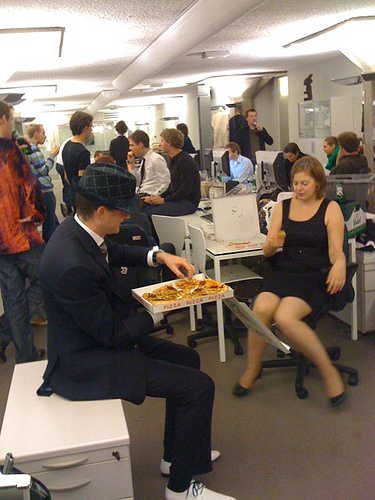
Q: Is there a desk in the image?
A: Yes, there is a desk.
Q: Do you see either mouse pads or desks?
A: Yes, there is a desk.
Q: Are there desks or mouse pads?
A: Yes, there is a desk.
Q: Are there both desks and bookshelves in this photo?
A: No, there is a desk but no bookshelves.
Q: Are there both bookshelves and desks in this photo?
A: No, there is a desk but no bookshelves.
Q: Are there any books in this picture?
A: No, there are no books.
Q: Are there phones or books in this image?
A: No, there are no books or phones.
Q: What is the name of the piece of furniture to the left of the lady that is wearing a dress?
A: The piece of furniture is a desk.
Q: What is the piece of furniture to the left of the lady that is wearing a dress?
A: The piece of furniture is a desk.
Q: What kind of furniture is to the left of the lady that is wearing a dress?
A: The piece of furniture is a desk.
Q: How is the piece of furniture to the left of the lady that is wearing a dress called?
A: The piece of furniture is a desk.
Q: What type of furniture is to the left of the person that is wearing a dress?
A: The piece of furniture is a desk.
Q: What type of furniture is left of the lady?
A: The piece of furniture is a desk.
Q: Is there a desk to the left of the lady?
A: Yes, there is a desk to the left of the lady.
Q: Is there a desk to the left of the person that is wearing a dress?
A: Yes, there is a desk to the left of the lady.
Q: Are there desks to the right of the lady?
A: No, the desk is to the left of the lady.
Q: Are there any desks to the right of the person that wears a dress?
A: No, the desk is to the left of the lady.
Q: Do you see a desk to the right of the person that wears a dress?
A: No, the desk is to the left of the lady.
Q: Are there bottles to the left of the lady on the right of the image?
A: No, there is a desk to the left of the lady.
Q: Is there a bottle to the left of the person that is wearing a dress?
A: No, there is a desk to the left of the lady.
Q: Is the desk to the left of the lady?
A: Yes, the desk is to the left of the lady.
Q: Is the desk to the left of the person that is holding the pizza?
A: Yes, the desk is to the left of the lady.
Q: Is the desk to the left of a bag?
A: No, the desk is to the left of the lady.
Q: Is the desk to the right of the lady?
A: No, the desk is to the left of the lady.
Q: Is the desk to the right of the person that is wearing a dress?
A: No, the desk is to the left of the lady.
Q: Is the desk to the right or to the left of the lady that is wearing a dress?
A: The desk is to the left of the lady.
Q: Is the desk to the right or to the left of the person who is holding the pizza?
A: The desk is to the left of the lady.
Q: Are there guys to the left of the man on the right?
A: Yes, there is a guy to the left of the man.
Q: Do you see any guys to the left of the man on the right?
A: Yes, there is a guy to the left of the man.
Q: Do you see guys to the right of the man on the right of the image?
A: No, the guy is to the left of the man.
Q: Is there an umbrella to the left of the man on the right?
A: No, there is a guy to the left of the man.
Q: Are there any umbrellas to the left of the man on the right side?
A: No, there is a guy to the left of the man.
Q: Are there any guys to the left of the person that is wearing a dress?
A: Yes, there is a guy to the left of the lady.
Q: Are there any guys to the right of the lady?
A: No, the guy is to the left of the lady.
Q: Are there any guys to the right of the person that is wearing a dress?
A: No, the guy is to the left of the lady.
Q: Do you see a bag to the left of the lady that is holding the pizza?
A: No, there is a guy to the left of the lady.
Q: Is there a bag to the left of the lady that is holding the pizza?
A: No, there is a guy to the left of the lady.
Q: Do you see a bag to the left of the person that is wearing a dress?
A: No, there is a guy to the left of the lady.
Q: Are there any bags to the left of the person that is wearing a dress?
A: No, there is a guy to the left of the lady.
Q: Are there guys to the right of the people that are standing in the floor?
A: Yes, there is a guy to the right of the people.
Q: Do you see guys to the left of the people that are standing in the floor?
A: No, the guy is to the right of the people.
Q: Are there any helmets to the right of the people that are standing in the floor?
A: No, there is a guy to the right of the people.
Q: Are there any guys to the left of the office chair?
A: Yes, there is a guy to the left of the office chair.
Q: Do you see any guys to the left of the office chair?
A: Yes, there is a guy to the left of the office chair.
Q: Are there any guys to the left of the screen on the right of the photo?
A: Yes, there is a guy to the left of the screen.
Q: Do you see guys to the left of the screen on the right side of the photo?
A: Yes, there is a guy to the left of the screen.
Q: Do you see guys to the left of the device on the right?
A: Yes, there is a guy to the left of the screen.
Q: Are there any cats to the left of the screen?
A: No, there is a guy to the left of the screen.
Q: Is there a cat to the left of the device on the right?
A: No, there is a guy to the left of the screen.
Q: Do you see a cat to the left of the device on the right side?
A: No, there is a guy to the left of the screen.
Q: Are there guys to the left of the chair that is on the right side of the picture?
A: Yes, there is a guy to the left of the chair.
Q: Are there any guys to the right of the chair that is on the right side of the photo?
A: No, the guy is to the left of the chair.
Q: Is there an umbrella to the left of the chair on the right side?
A: No, there is a guy to the left of the chair.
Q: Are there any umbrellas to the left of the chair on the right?
A: No, there is a guy to the left of the chair.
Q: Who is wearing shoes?
A: The guy is wearing shoes.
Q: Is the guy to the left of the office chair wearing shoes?
A: Yes, the guy is wearing shoes.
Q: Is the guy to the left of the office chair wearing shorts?
A: No, the guy is wearing shoes.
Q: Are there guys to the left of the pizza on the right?
A: Yes, there is a guy to the left of the pizza.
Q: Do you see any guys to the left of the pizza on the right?
A: Yes, there is a guy to the left of the pizza.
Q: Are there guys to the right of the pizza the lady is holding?
A: No, the guy is to the left of the pizza.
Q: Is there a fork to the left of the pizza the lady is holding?
A: No, there is a guy to the left of the pizza.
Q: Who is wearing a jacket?
A: The guy is wearing a jacket.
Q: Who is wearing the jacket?
A: The guy is wearing a jacket.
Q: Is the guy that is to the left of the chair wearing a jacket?
A: Yes, the guy is wearing a jacket.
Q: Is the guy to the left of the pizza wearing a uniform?
A: No, the guy is wearing a jacket.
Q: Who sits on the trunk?
A: The guy sits on the trunk.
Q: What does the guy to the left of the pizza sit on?
A: The guy sits on the trunk.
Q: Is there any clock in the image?
A: No, there are no clocks.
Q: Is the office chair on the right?
A: Yes, the office chair is on the right of the image.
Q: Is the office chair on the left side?
A: No, the office chair is on the right of the image.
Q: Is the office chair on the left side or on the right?
A: The office chair is on the right of the image.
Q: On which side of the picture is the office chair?
A: The office chair is on the right of the image.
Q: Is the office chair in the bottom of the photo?
A: Yes, the office chair is in the bottom of the image.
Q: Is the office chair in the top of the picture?
A: No, the office chair is in the bottom of the image.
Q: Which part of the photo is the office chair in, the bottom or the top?
A: The office chair is in the bottom of the image.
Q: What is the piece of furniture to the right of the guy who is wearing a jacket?
A: The piece of furniture is an office chair.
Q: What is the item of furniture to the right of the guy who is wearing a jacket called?
A: The piece of furniture is an office chair.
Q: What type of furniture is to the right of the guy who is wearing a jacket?
A: The piece of furniture is an office chair.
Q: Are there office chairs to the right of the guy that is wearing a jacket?
A: Yes, there is an office chair to the right of the guy.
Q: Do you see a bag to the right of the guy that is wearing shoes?
A: No, there is an office chair to the right of the guy.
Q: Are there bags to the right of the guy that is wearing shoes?
A: No, there is an office chair to the right of the guy.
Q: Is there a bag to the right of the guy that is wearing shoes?
A: No, there is an office chair to the right of the guy.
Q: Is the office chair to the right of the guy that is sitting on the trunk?
A: Yes, the office chair is to the right of the guy.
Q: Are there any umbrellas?
A: No, there are no umbrellas.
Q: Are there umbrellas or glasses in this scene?
A: No, there are no umbrellas or glasses.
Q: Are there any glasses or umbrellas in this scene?
A: No, there are no umbrellas or glasses.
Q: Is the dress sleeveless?
A: Yes, the dress is sleeveless.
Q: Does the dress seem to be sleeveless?
A: Yes, the dress is sleeveless.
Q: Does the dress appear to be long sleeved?
A: No, the dress is sleeveless.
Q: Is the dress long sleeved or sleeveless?
A: The dress is sleeveless.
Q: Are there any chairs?
A: Yes, there is a chair.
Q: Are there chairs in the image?
A: Yes, there is a chair.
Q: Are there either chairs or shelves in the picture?
A: Yes, there is a chair.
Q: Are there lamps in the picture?
A: No, there are no lamps.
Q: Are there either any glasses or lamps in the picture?
A: No, there are no lamps or glasses.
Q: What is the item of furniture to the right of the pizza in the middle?
A: The piece of furniture is a chair.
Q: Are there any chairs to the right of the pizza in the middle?
A: Yes, there is a chair to the right of the pizza.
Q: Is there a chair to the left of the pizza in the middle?
A: No, the chair is to the right of the pizza.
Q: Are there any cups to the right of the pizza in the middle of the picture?
A: No, there is a chair to the right of the pizza.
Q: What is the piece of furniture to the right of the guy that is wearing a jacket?
A: The piece of furniture is a chair.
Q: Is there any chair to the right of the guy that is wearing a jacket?
A: Yes, there is a chair to the right of the guy.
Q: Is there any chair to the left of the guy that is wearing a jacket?
A: No, the chair is to the right of the guy.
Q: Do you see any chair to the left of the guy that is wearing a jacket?
A: No, the chair is to the right of the guy.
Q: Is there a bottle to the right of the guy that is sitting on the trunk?
A: No, there is a chair to the right of the guy.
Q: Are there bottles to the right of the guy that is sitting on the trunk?
A: No, there is a chair to the right of the guy.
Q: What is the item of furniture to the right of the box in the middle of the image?
A: The piece of furniture is a chair.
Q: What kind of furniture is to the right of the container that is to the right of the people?
A: The piece of furniture is a chair.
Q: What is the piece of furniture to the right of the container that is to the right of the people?
A: The piece of furniture is a chair.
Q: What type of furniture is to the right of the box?
A: The piece of furniture is a chair.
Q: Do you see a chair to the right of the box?
A: Yes, there is a chair to the right of the box.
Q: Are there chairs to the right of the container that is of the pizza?
A: Yes, there is a chair to the right of the box.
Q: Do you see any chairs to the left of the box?
A: No, the chair is to the right of the box.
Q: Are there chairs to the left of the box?
A: No, the chair is to the right of the box.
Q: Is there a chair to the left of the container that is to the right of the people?
A: No, the chair is to the right of the box.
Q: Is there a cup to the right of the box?
A: No, there is a chair to the right of the box.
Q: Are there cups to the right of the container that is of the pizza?
A: No, there is a chair to the right of the box.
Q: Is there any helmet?
A: No, there are no helmets.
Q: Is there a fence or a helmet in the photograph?
A: No, there are no helmets or fences.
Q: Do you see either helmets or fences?
A: No, there are no helmets or fences.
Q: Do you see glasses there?
A: No, there are no glasses.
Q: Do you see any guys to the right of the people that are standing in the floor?
A: Yes, there is a guy to the right of the people.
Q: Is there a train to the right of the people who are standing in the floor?
A: No, there is a guy to the right of the people.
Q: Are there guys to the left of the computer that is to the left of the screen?
A: Yes, there is a guy to the left of the computer.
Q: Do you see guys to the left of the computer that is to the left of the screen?
A: Yes, there is a guy to the left of the computer.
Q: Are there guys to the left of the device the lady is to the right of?
A: Yes, there is a guy to the left of the computer.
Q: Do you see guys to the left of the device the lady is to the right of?
A: Yes, there is a guy to the left of the computer.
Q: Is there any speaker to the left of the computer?
A: No, there is a guy to the left of the computer.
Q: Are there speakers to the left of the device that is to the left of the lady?
A: No, there is a guy to the left of the computer.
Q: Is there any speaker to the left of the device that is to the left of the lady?
A: No, there is a guy to the left of the computer.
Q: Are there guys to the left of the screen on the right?
A: Yes, there is a guy to the left of the screen.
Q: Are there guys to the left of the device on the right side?
A: Yes, there is a guy to the left of the screen.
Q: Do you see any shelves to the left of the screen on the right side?
A: No, there is a guy to the left of the screen.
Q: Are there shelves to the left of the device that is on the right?
A: No, there is a guy to the left of the screen.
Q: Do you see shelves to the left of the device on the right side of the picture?
A: No, there is a guy to the left of the screen.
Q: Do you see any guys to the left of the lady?
A: Yes, there is a guy to the left of the lady.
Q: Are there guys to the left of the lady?
A: Yes, there is a guy to the left of the lady.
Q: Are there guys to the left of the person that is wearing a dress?
A: Yes, there is a guy to the left of the lady.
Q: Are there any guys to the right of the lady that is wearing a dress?
A: No, the guy is to the left of the lady.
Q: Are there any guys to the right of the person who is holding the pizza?
A: No, the guy is to the left of the lady.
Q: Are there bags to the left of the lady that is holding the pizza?
A: No, there is a guy to the left of the lady.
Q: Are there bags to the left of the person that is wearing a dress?
A: No, there is a guy to the left of the lady.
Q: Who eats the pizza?
A: The guy eats the pizza.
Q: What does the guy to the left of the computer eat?
A: The guy eats a pizza.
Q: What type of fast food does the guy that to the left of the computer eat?
A: The guy eats a pizza.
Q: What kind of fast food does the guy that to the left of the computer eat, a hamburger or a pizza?
A: The guy eats a pizza.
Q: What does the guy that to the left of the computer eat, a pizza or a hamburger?
A: The guy eats a pizza.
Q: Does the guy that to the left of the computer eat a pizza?
A: Yes, the guy eats a pizza.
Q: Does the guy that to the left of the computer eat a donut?
A: No, the guy eats a pizza.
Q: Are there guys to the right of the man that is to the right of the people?
A: Yes, there is a guy to the right of the man.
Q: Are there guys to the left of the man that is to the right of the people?
A: No, the guy is to the right of the man.